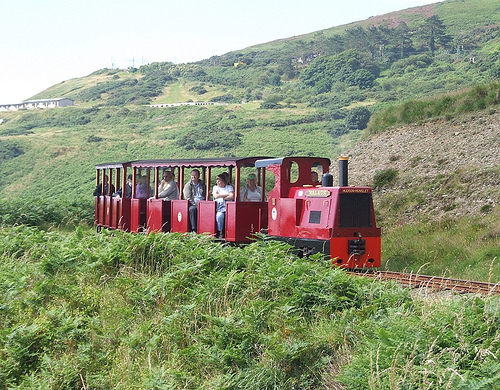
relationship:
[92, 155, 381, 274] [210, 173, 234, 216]
train carrying passenger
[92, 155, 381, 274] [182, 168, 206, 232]
train carrying man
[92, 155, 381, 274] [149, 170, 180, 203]
train carrying man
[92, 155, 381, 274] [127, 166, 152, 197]
train carrying passenger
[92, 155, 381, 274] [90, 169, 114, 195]
train carrying passenger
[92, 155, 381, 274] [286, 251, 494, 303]
train on tracks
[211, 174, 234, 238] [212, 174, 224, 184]
passenger with shades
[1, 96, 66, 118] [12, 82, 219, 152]
building on top of hill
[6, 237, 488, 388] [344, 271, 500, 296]
grass along tracks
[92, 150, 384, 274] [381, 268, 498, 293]
train moving along tracks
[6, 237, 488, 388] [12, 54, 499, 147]
grass growing along countryside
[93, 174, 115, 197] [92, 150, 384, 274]
passenger riding on train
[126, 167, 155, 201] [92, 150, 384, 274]
person riding on train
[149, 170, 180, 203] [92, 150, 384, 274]
man riding on train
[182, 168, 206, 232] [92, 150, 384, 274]
man riding on train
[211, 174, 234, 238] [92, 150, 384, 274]
passenger riding on train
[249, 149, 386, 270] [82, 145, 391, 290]
engine of train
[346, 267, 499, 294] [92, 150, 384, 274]
tracks for train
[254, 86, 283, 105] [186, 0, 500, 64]
tree on hill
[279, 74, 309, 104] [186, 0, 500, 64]
tree on hill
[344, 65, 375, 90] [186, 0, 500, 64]
tree on hill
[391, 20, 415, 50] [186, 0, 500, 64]
tree on hill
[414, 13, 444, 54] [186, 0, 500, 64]
tree on hill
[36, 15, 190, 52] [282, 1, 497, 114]
sky above mountain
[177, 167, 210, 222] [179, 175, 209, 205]
man wearing jacket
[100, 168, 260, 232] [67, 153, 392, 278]
people on train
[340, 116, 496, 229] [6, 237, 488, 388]
rocks are next to grass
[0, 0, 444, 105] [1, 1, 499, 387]
sky above land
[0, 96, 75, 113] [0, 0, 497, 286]
building on hillside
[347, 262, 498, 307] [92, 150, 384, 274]
tracks are in front of train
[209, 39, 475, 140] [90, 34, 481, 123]
hill full of trees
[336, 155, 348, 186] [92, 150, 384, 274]
black funnel on front of train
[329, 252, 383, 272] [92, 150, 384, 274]
holes are in front of train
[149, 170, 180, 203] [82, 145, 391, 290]
man sitting in train